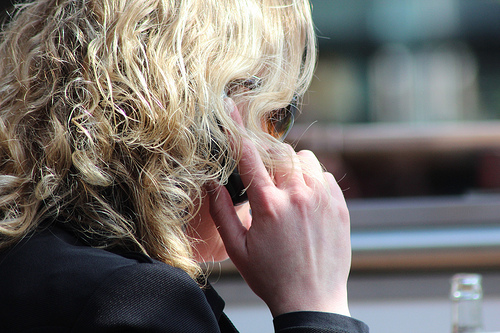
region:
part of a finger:
[258, 183, 278, 233]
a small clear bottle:
[452, 273, 481, 331]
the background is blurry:
[198, 1, 498, 331]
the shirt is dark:
[0, 205, 367, 332]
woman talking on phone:
[0, 2, 367, 332]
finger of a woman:
[221, 96, 268, 185]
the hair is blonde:
[0, 3, 319, 287]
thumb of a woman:
[204, 179, 246, 261]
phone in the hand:
[198, 108, 255, 201]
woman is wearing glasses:
[232, 71, 294, 141]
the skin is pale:
[187, 68, 349, 318]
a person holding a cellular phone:
[185, 71, 356, 304]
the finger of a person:
[209, 93, 274, 195]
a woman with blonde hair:
[3, 4, 317, 233]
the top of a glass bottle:
[446, 270, 488, 329]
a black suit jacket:
[0, 180, 236, 332]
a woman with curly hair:
[2, 3, 284, 238]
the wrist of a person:
[262, 280, 354, 317]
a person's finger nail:
[222, 95, 234, 113]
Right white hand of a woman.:
[203, 95, 353, 290]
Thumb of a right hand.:
[201, 172, 243, 247]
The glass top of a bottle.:
[449, 271, 482, 332]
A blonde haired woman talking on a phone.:
[0, 0, 367, 332]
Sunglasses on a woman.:
[226, 77, 297, 143]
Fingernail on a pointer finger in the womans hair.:
[220, 98, 233, 115]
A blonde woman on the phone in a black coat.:
[1, 0, 368, 332]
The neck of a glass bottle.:
[452, 297, 482, 332]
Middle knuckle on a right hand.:
[291, 187, 307, 211]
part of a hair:
[79, 165, 101, 175]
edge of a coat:
[318, 306, 333, 322]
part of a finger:
[274, 202, 284, 213]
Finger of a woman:
[198, 168, 243, 249]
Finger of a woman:
[200, 164, 248, 251]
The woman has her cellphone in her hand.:
[179, 112, 256, 207]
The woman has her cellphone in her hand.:
[185, 98, 259, 210]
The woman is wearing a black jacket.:
[2, 214, 367, 331]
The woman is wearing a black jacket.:
[0, 222, 352, 329]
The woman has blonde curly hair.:
[6, 7, 291, 275]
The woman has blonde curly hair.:
[6, 7, 306, 260]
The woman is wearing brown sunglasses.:
[233, 89, 292, 138]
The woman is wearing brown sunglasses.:
[233, 73, 304, 135]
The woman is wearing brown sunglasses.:
[238, 68, 299, 137]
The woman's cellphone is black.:
[184, 105, 248, 201]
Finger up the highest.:
[221, 96, 274, 201]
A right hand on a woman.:
[201, 98, 350, 315]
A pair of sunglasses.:
[226, 76, 298, 143]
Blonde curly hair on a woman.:
[0, 2, 315, 287]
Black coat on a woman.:
[1, 211, 369, 331]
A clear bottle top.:
[448, 274, 484, 332]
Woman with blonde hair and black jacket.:
[2, 1, 365, 331]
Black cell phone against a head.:
[197, 113, 251, 205]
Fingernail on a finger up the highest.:
[220, 99, 235, 112]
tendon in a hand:
[298, 213, 315, 274]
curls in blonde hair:
[121, 110, 213, 252]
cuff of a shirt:
[273, 297, 367, 331]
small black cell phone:
[191, 120, 271, 198]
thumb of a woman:
[203, 185, 241, 241]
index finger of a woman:
[226, 105, 257, 183]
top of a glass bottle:
[446, 268, 489, 328]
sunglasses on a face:
[250, 72, 316, 148]